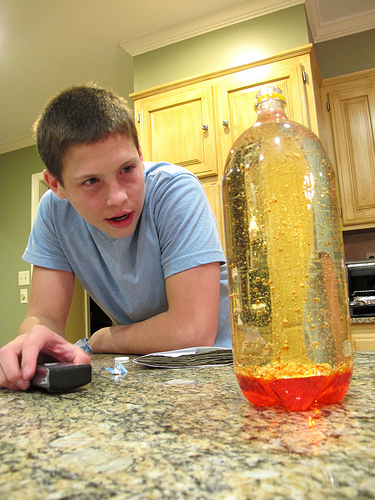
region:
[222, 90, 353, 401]
a glass bottle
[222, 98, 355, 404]
a bottle with a red liquid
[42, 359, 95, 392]
a black mobile phone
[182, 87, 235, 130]
a brown wooden cupboard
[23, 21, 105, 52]
a white wooden ceiling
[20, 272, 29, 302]
two white wall sockets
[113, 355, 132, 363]
a white tablet of medicine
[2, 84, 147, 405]
a boy holding a mobile phone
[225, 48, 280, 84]
reflection of a light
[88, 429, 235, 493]
a shiny black and white surface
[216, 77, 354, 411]
A plastic bottle with liquid in it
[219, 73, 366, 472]
A bottle on top of the counter top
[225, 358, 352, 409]
Red liquid seperated on the bottles bottom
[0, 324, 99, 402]
The boy holds onto an object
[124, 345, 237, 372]
An envelope full of money on the counter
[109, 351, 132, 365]
The lid to the plastic bottle.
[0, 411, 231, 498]
The marble counter top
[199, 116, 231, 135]
Round knobs on the doors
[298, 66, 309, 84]
The metal hinges on the door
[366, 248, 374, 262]
The socket on the wall with a plug in it.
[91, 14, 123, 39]
part of a ceiling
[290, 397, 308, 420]
part of a bottle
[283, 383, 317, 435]
part of a bottle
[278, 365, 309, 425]
part of a bottle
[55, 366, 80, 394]
edge of a remote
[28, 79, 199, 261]
kid in the photo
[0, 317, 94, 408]
hand of the kid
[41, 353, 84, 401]
object on the table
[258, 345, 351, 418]
liquid in the bottle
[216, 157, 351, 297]
empty part of the bottle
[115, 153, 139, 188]
eye of the kid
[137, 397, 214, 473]
design on the table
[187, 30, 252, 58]
green wall above the kid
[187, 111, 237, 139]
knobs on the door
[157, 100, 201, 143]
brown door behind kid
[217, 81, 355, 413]
Two liter plastic bottle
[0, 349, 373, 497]
Mixed color granite counter top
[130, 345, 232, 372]
Envelope filled with money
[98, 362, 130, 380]
Opened paper wrapper on the counter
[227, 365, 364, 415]
Red liquid inside a bottle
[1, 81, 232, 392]
Boy leaning against the counter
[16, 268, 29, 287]
Light switch on the wall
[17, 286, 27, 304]
Light dimmer knob on the wall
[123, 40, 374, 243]
Wooden cabinets in the wall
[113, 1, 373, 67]
Crown molding between the wall and ceiling